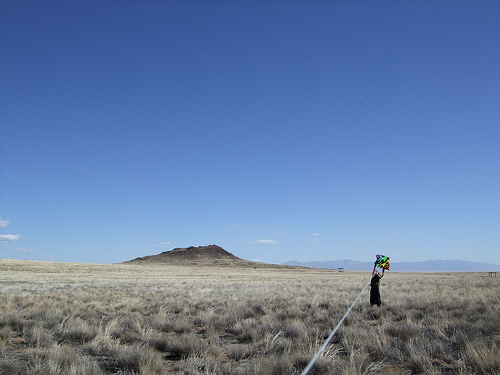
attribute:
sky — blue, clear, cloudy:
[463, 11, 485, 23]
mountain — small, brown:
[125, 230, 236, 281]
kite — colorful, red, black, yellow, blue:
[373, 250, 393, 275]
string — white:
[299, 345, 337, 360]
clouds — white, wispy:
[3, 194, 32, 257]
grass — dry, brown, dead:
[455, 304, 488, 346]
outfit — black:
[368, 276, 387, 309]